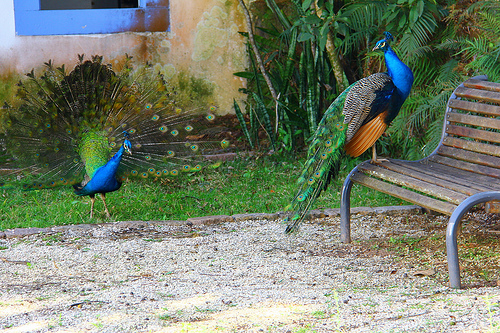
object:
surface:
[106, 232, 387, 302]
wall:
[0, 0, 251, 164]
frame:
[12, 20, 172, 47]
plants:
[222, 0, 301, 154]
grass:
[16, 191, 64, 220]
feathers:
[345, 120, 383, 154]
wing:
[277, 75, 388, 234]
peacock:
[278, 29, 411, 240]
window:
[11, 0, 167, 36]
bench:
[336, 76, 500, 292]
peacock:
[0, 53, 228, 222]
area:
[2, 7, 500, 333]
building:
[1, 0, 278, 175]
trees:
[299, 0, 347, 94]